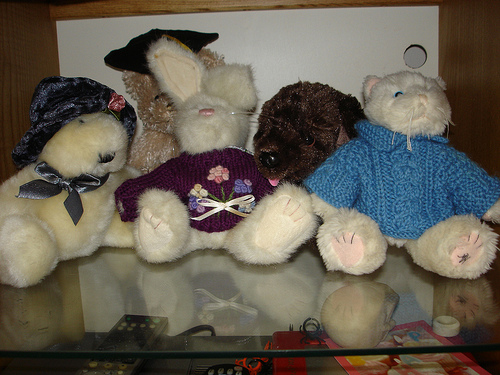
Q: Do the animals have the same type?
A: No, they are spiders and cats.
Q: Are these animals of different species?
A: Yes, they are spiders and cats.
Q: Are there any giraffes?
A: No, there are no giraffes.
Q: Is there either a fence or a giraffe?
A: No, there are no giraffes or fences.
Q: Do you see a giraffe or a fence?
A: No, there are no giraffes or fences.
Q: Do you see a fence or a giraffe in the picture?
A: No, there are no giraffes or fences.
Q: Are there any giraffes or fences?
A: No, there are no giraffes or fences.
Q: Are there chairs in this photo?
A: No, there are no chairs.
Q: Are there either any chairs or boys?
A: No, there are no chairs or boys.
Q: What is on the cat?
A: The sweater is on the cat.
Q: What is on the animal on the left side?
A: The sweater is on the cat.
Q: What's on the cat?
A: The sweater is on the cat.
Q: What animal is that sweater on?
A: The sweater is on the cat.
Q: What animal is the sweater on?
A: The sweater is on the cat.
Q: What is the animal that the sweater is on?
A: The animal is a cat.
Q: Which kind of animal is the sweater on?
A: The sweater is on the cat.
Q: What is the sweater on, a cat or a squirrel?
A: The sweater is on a cat.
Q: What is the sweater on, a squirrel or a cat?
A: The sweater is on a cat.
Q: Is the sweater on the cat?
A: Yes, the sweater is on the cat.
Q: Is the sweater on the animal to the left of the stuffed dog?
A: Yes, the sweater is on the cat.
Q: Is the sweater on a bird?
A: No, the sweater is on the cat.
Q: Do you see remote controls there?
A: Yes, there is a remote control.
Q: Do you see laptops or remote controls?
A: Yes, there is a remote control.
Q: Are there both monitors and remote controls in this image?
A: No, there is a remote control but no monitors.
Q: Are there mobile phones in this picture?
A: No, there are no mobile phones.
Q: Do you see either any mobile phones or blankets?
A: No, there are no mobile phones or blankets.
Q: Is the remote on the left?
A: Yes, the remote is on the left of the image.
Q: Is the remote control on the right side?
A: No, the remote control is on the left of the image.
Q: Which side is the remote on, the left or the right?
A: The remote is on the left of the image.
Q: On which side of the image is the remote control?
A: The remote control is on the left of the image.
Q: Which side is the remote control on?
A: The remote control is on the left of the image.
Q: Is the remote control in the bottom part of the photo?
A: Yes, the remote control is in the bottom of the image.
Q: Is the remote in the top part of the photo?
A: No, the remote is in the bottom of the image.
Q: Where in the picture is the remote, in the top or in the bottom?
A: The remote is in the bottom of the image.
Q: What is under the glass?
A: The remote is under the glass.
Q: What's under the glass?
A: The remote is under the glass.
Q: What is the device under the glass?
A: The device is a remote control.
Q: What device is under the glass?
A: The device is a remote control.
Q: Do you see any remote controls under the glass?
A: Yes, there is a remote control under the glass.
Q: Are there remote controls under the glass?
A: Yes, there is a remote control under the glass.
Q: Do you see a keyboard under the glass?
A: No, there is a remote control under the glass.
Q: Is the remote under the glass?
A: Yes, the remote is under the glass.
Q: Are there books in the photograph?
A: No, there are no books.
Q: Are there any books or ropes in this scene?
A: No, there are no books or ropes.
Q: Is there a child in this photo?
A: No, there are no children.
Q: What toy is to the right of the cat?
A: The toy is a stuffed dog.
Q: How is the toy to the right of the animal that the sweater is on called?
A: The toy is a stuffed dog.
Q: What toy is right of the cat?
A: The toy is a stuffed dog.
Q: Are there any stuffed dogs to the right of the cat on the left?
A: Yes, there is a stuffed dog to the right of the cat.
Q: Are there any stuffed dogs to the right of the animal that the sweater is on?
A: Yes, there is a stuffed dog to the right of the cat.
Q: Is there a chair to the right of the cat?
A: No, there is a stuffed dog to the right of the cat.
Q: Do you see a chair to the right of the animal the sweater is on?
A: No, there is a stuffed dog to the right of the cat.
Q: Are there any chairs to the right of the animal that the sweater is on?
A: No, there is a stuffed dog to the right of the cat.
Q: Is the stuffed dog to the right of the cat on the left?
A: Yes, the stuffed dog is to the right of the cat.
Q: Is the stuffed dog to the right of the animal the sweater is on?
A: Yes, the stuffed dog is to the right of the cat.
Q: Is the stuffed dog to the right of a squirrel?
A: No, the stuffed dog is to the right of the cat.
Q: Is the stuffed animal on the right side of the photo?
A: Yes, the stuffed animal is on the right of the image.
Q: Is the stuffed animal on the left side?
A: No, the stuffed animal is on the right of the image.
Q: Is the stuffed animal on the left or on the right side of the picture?
A: The stuffed animal is on the right of the image.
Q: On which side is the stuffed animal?
A: The stuffed animal is on the right of the image.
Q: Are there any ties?
A: Yes, there is a tie.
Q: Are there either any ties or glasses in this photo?
A: Yes, there is a tie.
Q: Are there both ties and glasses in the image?
A: Yes, there are both a tie and glasses.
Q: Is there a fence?
A: No, there are no fences.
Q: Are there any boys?
A: No, there are no boys.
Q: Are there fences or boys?
A: No, there are no boys or fences.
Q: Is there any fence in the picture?
A: No, there are no fences.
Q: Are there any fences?
A: No, there are no fences.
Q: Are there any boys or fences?
A: No, there are no fences or boys.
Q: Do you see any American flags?
A: No, there are no American flags.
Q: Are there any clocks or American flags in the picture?
A: No, there are no American flags or clocks.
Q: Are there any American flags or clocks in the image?
A: No, there are no American flags or clocks.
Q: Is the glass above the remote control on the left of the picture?
A: Yes, the glass is above the remote.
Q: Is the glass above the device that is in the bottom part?
A: Yes, the glass is above the remote.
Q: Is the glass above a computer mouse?
A: No, the glass is above the remote.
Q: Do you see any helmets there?
A: No, there are no helmets.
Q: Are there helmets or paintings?
A: No, there are no helmets or paintings.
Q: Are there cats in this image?
A: Yes, there is a cat.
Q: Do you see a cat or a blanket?
A: Yes, there is a cat.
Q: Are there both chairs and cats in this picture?
A: No, there is a cat but no chairs.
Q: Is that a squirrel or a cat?
A: That is a cat.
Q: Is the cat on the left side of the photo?
A: Yes, the cat is on the left of the image.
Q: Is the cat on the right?
A: No, the cat is on the left of the image.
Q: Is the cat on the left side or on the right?
A: The cat is on the left of the image.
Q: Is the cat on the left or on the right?
A: The cat is on the left of the image.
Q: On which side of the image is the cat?
A: The cat is on the left of the image.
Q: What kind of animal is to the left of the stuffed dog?
A: The animal is a cat.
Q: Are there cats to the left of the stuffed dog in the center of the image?
A: Yes, there is a cat to the left of the stuffed dog.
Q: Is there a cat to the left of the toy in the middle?
A: Yes, there is a cat to the left of the stuffed dog.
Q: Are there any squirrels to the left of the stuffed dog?
A: No, there is a cat to the left of the stuffed dog.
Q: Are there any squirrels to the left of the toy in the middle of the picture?
A: No, there is a cat to the left of the stuffed dog.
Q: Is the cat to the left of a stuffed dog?
A: Yes, the cat is to the left of a stuffed dog.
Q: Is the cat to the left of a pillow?
A: No, the cat is to the left of a stuffed dog.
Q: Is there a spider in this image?
A: Yes, there is a spider.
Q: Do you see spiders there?
A: Yes, there is a spider.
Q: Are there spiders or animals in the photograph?
A: Yes, there is a spider.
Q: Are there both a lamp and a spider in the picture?
A: No, there is a spider but no lamps.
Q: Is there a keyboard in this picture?
A: No, there are no keyboards.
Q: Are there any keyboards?
A: No, there are no keyboards.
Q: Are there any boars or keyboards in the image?
A: No, there are no keyboards or boars.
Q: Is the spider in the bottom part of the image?
A: Yes, the spider is in the bottom of the image.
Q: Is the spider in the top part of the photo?
A: No, the spider is in the bottom of the image.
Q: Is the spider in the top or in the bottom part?
A: The spider is in the bottom of the image.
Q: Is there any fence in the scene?
A: No, there are no fences.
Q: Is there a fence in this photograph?
A: No, there are no fences.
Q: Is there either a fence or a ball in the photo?
A: No, there are no fences or balls.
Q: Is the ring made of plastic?
A: Yes, the ring is made of plastic.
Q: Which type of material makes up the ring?
A: The ring is made of plastic.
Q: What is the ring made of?
A: The ring is made of plastic.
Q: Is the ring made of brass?
A: No, the ring is made of plastic.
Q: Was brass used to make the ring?
A: No, the ring is made of plastic.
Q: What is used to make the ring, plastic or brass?
A: The ring is made of plastic.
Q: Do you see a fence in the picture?
A: No, there are no fences.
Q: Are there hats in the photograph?
A: Yes, there is a hat.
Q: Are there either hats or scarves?
A: Yes, there is a hat.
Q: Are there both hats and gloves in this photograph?
A: No, there is a hat but no gloves.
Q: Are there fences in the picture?
A: No, there are no fences.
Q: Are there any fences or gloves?
A: No, there are no fences or gloves.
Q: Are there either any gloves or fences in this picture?
A: No, there are no fences or gloves.